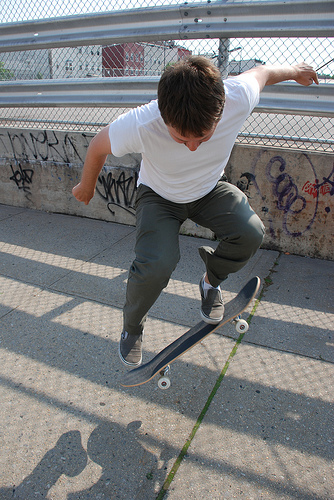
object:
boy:
[71, 47, 319, 369]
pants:
[123, 176, 266, 335]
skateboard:
[119, 275, 261, 391]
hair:
[157, 56, 227, 139]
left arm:
[242, 65, 301, 107]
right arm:
[82, 110, 136, 194]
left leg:
[192, 181, 267, 289]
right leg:
[123, 194, 181, 334]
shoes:
[118, 323, 144, 368]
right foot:
[118, 327, 144, 367]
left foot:
[198, 272, 225, 325]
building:
[0, 46, 104, 78]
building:
[102, 43, 144, 77]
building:
[143, 45, 164, 76]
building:
[178, 47, 192, 60]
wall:
[0, 105, 333, 260]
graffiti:
[6, 130, 84, 164]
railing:
[0, 0, 333, 107]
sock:
[201, 273, 220, 290]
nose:
[187, 137, 200, 152]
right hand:
[71, 181, 95, 205]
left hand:
[296, 61, 319, 87]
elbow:
[259, 65, 273, 88]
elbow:
[88, 134, 107, 162]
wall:
[5, 49, 55, 78]